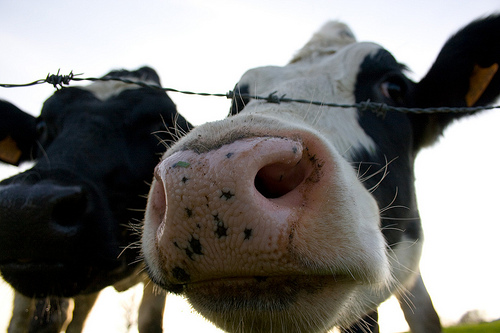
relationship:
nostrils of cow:
[146, 130, 326, 256] [136, 1, 493, 330]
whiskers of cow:
[344, 151, 408, 224] [136, 1, 493, 330]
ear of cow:
[411, 13, 499, 147] [136, 1, 493, 330]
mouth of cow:
[153, 241, 358, 303] [136, 1, 493, 330]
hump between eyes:
[278, 16, 362, 65] [224, 75, 406, 123]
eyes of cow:
[224, 75, 406, 123] [136, 1, 493, 330]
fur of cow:
[374, 133, 413, 207] [136, 1, 493, 330]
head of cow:
[135, 15, 499, 333] [136, 1, 493, 330]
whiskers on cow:
[344, 151, 408, 224] [136, 1, 493, 330]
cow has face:
[136, 1, 493, 330] [141, 72, 408, 333]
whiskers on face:
[344, 151, 408, 224] [141, 72, 408, 333]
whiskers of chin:
[194, 300, 368, 333] [164, 276, 367, 333]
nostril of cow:
[44, 182, 91, 234] [1, 60, 187, 306]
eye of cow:
[378, 70, 410, 114] [136, 1, 493, 330]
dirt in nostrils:
[302, 146, 330, 195] [146, 130, 326, 256]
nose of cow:
[2, 181, 92, 265] [1, 60, 187, 306]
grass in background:
[426, 320, 499, 331] [420, 255, 492, 256]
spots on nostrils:
[169, 188, 248, 256] [146, 130, 326, 256]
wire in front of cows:
[2, 62, 497, 134] [1, 10, 480, 329]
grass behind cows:
[426, 320, 499, 331] [1, 10, 480, 329]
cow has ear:
[136, 1, 493, 330] [411, 13, 499, 147]